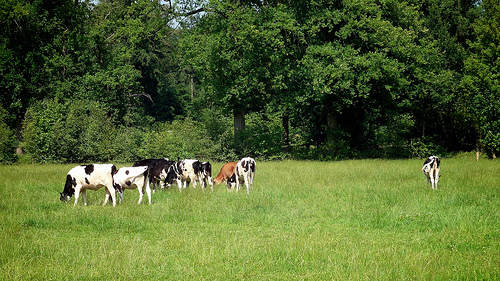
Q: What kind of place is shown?
A: It is a field.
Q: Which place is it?
A: It is a field.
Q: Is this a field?
A: Yes, it is a field.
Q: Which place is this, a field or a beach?
A: It is a field.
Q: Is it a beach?
A: No, it is a field.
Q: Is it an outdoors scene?
A: Yes, it is outdoors.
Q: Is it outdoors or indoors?
A: It is outdoors.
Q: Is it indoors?
A: No, it is outdoors.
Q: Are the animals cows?
A: Yes, all the animals are cows.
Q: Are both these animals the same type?
A: Yes, all the animals are cows.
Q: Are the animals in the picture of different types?
A: No, all the animals are cows.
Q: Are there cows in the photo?
A: Yes, there is a cow.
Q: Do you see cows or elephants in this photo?
A: Yes, there is a cow.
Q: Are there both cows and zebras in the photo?
A: No, there is a cow but no zebras.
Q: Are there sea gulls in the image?
A: No, there are no sea gulls.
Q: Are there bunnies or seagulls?
A: No, there are no seagulls or bunnies.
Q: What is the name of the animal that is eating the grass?
A: The animal is a cow.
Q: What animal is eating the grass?
A: The animal is a cow.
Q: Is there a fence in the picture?
A: No, there are no fences.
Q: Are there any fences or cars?
A: No, there are no fences or cars.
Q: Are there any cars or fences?
A: No, there are no fences or cars.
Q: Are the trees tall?
A: Yes, the trees are tall.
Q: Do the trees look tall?
A: Yes, the trees are tall.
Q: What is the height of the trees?
A: The trees are tall.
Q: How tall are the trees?
A: The trees are tall.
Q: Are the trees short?
A: No, the trees are tall.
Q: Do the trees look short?
A: No, the trees are tall.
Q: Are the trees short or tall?
A: The trees are tall.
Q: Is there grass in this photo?
A: Yes, there is grass.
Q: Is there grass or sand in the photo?
A: Yes, there is grass.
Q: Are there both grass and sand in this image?
A: No, there is grass but no sand.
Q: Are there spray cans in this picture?
A: No, there are no spray cans.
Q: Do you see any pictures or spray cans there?
A: No, there are no spray cans or pictures.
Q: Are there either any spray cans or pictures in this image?
A: No, there are no spray cans or pictures.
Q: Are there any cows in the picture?
A: Yes, there is a cow.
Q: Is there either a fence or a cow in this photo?
A: Yes, there is a cow.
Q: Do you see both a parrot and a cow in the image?
A: No, there is a cow but no parrots.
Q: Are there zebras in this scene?
A: No, there are no zebras.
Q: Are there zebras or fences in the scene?
A: No, there are no zebras or fences.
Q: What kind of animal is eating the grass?
A: The animal is a cow.